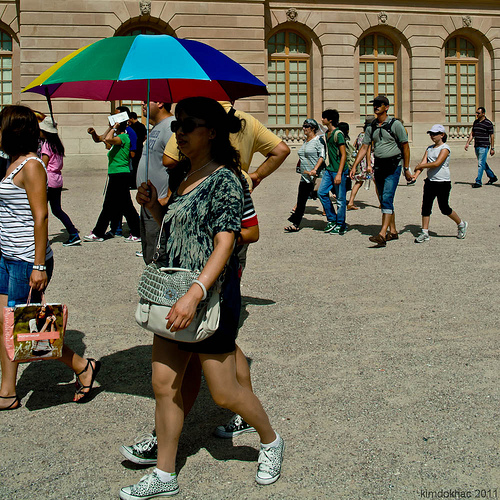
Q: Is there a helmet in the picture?
A: No, there are no helmets.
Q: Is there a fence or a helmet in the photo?
A: No, there are no helmets or fences.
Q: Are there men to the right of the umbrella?
A: Yes, there is a man to the right of the umbrella.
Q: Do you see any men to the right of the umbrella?
A: Yes, there is a man to the right of the umbrella.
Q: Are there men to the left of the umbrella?
A: No, the man is to the right of the umbrella.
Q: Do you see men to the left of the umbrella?
A: No, the man is to the right of the umbrella.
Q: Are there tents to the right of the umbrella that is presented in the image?
A: No, there is a man to the right of the umbrella.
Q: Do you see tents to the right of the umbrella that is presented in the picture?
A: No, there is a man to the right of the umbrella.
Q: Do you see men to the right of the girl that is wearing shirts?
A: Yes, there is a man to the right of the girl.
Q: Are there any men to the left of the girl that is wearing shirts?
A: No, the man is to the right of the girl.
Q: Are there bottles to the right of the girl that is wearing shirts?
A: No, there is a man to the right of the girl.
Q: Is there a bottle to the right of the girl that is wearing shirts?
A: No, there is a man to the right of the girl.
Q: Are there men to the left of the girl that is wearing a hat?
A: Yes, there is a man to the left of the girl.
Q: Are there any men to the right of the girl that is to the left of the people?
A: No, the man is to the left of the girl.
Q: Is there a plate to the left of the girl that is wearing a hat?
A: No, there is a man to the left of the girl.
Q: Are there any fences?
A: No, there are no fences.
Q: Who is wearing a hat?
A: The girl is wearing a hat.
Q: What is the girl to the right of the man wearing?
A: The girl is wearing a hat.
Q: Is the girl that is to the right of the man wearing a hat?
A: Yes, the girl is wearing a hat.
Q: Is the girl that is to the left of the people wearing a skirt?
A: No, the girl is wearing a hat.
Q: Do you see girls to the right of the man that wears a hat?
A: Yes, there is a girl to the right of the man.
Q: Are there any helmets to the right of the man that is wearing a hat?
A: No, there is a girl to the right of the man.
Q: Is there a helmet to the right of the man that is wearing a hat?
A: No, there is a girl to the right of the man.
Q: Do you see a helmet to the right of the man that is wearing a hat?
A: No, there is a girl to the right of the man.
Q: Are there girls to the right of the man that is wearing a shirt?
A: Yes, there is a girl to the right of the man.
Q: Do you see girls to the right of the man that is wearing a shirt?
A: Yes, there is a girl to the right of the man.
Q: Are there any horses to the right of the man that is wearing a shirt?
A: No, there is a girl to the right of the man.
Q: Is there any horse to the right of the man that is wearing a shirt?
A: No, there is a girl to the right of the man.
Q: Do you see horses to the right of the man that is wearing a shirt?
A: No, there is a girl to the right of the man.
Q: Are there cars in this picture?
A: No, there are no cars.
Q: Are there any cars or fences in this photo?
A: No, there are no cars or fences.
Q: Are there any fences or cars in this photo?
A: No, there are no cars or fences.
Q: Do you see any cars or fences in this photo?
A: No, there are no cars or fences.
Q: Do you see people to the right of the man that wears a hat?
A: Yes, there are people to the right of the man.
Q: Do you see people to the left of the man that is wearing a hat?
A: No, the people are to the right of the man.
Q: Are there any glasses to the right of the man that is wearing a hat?
A: No, there are people to the right of the man.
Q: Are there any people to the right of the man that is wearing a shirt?
A: Yes, there are people to the right of the man.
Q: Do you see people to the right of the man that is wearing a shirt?
A: Yes, there are people to the right of the man.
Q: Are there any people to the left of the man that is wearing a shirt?
A: No, the people are to the right of the man.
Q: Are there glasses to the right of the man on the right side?
A: No, there are people to the right of the man.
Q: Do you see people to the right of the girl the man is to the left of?
A: Yes, there are people to the right of the girl.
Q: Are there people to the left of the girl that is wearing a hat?
A: No, the people are to the right of the girl.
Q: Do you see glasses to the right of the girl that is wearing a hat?
A: No, there are people to the right of the girl.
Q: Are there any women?
A: Yes, there is a woman.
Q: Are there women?
A: Yes, there is a woman.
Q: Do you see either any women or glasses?
A: Yes, there is a woman.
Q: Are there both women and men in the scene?
A: Yes, there are both a woman and a man.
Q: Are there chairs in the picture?
A: No, there are no chairs.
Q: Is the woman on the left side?
A: Yes, the woman is on the left of the image.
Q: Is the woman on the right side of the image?
A: No, the woman is on the left of the image.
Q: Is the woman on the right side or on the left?
A: The woman is on the left of the image.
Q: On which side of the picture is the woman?
A: The woman is on the left of the image.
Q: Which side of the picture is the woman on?
A: The woman is on the left of the image.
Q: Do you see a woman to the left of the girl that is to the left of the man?
A: Yes, there is a woman to the left of the girl.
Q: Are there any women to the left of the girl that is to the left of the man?
A: Yes, there is a woman to the left of the girl.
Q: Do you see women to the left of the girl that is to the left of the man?
A: Yes, there is a woman to the left of the girl.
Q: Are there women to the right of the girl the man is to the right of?
A: No, the woman is to the left of the girl.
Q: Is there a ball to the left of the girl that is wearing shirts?
A: No, there is a woman to the left of the girl.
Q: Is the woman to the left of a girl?
A: Yes, the woman is to the left of a girl.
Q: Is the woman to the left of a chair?
A: No, the woman is to the left of a girl.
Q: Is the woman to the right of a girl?
A: No, the woman is to the left of a girl.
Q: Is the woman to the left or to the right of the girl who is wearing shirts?
A: The woman is to the left of the girl.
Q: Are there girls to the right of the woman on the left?
A: Yes, there is a girl to the right of the woman.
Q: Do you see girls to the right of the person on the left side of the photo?
A: Yes, there is a girl to the right of the woman.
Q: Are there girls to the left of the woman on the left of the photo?
A: No, the girl is to the right of the woman.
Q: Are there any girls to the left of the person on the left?
A: No, the girl is to the right of the woman.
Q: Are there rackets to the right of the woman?
A: No, there is a girl to the right of the woman.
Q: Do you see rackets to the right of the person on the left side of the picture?
A: No, there is a girl to the right of the woman.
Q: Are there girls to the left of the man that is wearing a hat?
A: Yes, there is a girl to the left of the man.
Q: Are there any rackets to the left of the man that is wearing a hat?
A: No, there is a girl to the left of the man.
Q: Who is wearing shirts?
A: The girl is wearing shirts.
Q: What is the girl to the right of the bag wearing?
A: The girl is wearing shirts.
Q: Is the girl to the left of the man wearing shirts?
A: Yes, the girl is wearing shirts.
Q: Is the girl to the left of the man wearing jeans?
A: No, the girl is wearing shirts.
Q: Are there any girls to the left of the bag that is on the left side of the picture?
A: No, the girl is to the right of the bag.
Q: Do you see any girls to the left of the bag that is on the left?
A: No, the girl is to the right of the bag.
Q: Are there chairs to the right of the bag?
A: No, there is a girl to the right of the bag.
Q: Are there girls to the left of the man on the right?
A: Yes, there is a girl to the left of the man.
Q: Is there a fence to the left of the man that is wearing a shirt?
A: No, there is a girl to the left of the man.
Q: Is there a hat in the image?
A: Yes, there is a hat.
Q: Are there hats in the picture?
A: Yes, there is a hat.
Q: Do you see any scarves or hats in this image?
A: Yes, there is a hat.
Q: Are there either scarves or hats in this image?
A: Yes, there is a hat.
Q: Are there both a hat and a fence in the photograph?
A: No, there is a hat but no fences.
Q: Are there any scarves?
A: No, there are no scarves.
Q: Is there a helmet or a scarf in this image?
A: No, there are no scarves or helmets.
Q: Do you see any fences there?
A: No, there are no fences.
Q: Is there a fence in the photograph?
A: No, there are no fences.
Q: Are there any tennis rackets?
A: No, there are no tennis rackets.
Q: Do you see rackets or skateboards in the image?
A: No, there are no rackets or skateboards.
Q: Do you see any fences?
A: No, there are no fences.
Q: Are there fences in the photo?
A: No, there are no fences.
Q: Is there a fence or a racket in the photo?
A: No, there are no fences or rackets.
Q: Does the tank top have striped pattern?
A: Yes, the tank top is striped.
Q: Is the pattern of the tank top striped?
A: Yes, the tank top is striped.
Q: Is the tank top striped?
A: Yes, the tank top is striped.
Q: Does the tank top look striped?
A: Yes, the tank top is striped.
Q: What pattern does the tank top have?
A: The tank top has striped pattern.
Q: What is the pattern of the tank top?
A: The tank top is striped.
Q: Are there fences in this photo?
A: No, there are no fences.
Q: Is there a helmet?
A: No, there are no helmets.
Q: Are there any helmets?
A: No, there are no helmets.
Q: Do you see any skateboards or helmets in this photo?
A: No, there are no helmets or skateboards.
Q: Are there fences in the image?
A: No, there are no fences.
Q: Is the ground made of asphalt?
A: Yes, the ground is made of asphalt.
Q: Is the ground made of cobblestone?
A: No, the ground is made of asphalt.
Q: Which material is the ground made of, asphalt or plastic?
A: The ground is made of asphalt.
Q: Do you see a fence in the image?
A: No, there are no fences.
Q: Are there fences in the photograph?
A: No, there are no fences.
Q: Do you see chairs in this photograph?
A: No, there are no chairs.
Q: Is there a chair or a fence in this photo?
A: No, there are no chairs or fences.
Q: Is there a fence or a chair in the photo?
A: No, there are no chairs or fences.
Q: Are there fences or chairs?
A: No, there are no chairs or fences.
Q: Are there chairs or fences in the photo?
A: No, there are no chairs or fences.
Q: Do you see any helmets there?
A: No, there are no helmets.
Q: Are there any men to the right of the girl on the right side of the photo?
A: No, the man is to the left of the girl.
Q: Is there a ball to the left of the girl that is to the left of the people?
A: No, there is a man to the left of the girl.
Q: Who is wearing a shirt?
A: The man is wearing a shirt.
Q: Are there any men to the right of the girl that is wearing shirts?
A: Yes, there is a man to the right of the girl.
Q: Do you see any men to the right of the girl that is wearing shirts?
A: Yes, there is a man to the right of the girl.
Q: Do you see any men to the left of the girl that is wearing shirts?
A: No, the man is to the right of the girl.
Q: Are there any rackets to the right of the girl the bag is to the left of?
A: No, there is a man to the right of the girl.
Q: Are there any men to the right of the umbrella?
A: Yes, there is a man to the right of the umbrella.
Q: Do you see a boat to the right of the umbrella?
A: No, there is a man to the right of the umbrella.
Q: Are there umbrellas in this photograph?
A: Yes, there is an umbrella.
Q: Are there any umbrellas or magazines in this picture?
A: Yes, there is an umbrella.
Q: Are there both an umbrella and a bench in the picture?
A: No, there is an umbrella but no benches.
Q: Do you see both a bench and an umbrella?
A: No, there is an umbrella but no benches.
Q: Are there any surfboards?
A: No, there are no surfboards.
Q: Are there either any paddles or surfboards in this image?
A: No, there are no surfboards or paddles.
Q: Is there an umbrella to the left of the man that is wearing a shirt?
A: Yes, there is an umbrella to the left of the man.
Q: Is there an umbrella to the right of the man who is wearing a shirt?
A: No, the umbrella is to the left of the man.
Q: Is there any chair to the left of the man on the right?
A: No, there is an umbrella to the left of the man.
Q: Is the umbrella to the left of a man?
A: Yes, the umbrella is to the left of a man.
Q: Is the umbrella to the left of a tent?
A: No, the umbrella is to the left of a man.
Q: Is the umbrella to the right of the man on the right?
A: No, the umbrella is to the left of the man.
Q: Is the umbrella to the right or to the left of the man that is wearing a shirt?
A: The umbrella is to the left of the man.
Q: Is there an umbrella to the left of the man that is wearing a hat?
A: Yes, there is an umbrella to the left of the man.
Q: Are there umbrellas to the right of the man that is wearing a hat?
A: No, the umbrella is to the left of the man.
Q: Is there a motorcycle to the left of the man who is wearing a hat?
A: No, there is an umbrella to the left of the man.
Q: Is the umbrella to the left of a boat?
A: No, the umbrella is to the left of a man.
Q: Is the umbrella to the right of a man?
A: No, the umbrella is to the left of a man.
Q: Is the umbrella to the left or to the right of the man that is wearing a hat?
A: The umbrella is to the left of the man.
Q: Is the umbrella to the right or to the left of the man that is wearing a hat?
A: The umbrella is to the left of the man.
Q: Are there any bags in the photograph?
A: Yes, there is a bag.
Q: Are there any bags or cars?
A: Yes, there is a bag.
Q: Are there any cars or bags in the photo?
A: Yes, there is a bag.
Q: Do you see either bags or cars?
A: Yes, there is a bag.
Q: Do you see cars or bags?
A: Yes, there is a bag.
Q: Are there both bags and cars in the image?
A: No, there is a bag but no cars.